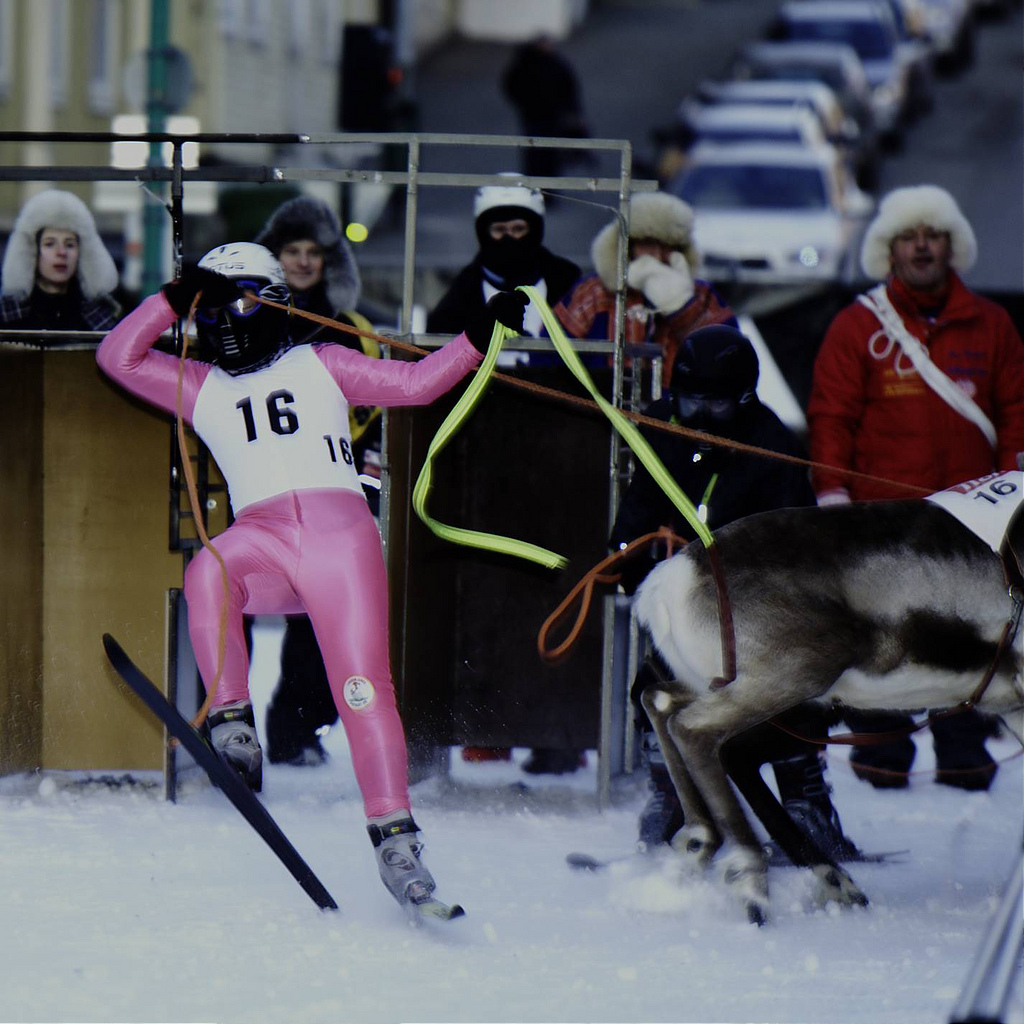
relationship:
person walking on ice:
[610, 327, 865, 865] [7, 770, 1021, 1023]